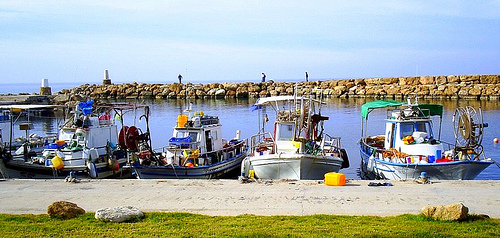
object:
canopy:
[357, 99, 447, 147]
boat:
[355, 98, 496, 180]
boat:
[237, 93, 350, 180]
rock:
[45, 200, 87, 220]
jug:
[322, 171, 347, 187]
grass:
[0, 214, 498, 237]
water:
[0, 98, 498, 181]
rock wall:
[56, 75, 499, 100]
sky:
[0, 1, 497, 84]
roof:
[250, 95, 328, 107]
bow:
[248, 155, 343, 179]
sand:
[0, 176, 499, 213]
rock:
[420, 201, 469, 222]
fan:
[450, 104, 490, 161]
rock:
[92, 204, 145, 222]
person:
[176, 73, 183, 84]